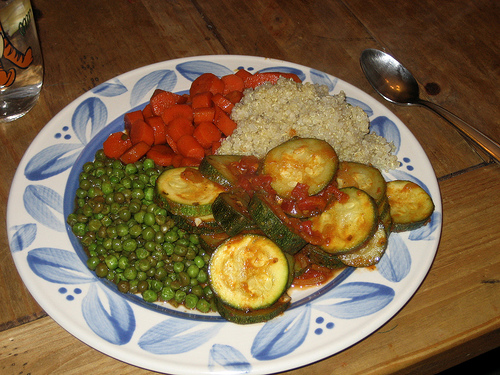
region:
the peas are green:
[107, 213, 219, 337]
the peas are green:
[79, 182, 171, 287]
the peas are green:
[65, 154, 202, 314]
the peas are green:
[125, 279, 214, 369]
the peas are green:
[99, 187, 276, 347]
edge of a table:
[436, 322, 468, 348]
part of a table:
[445, 251, 471, 296]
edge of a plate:
[358, 270, 405, 325]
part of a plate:
[151, 330, 175, 350]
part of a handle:
[466, 120, 489, 158]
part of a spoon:
[418, 93, 452, 120]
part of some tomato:
[283, 183, 315, 215]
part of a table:
[438, 268, 471, 308]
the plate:
[179, 310, 259, 373]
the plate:
[197, 296, 259, 316]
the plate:
[204, 290, 255, 338]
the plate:
[185, 285, 265, 356]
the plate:
[179, 301, 242, 341]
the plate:
[214, 287, 271, 373]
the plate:
[177, 247, 254, 307]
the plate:
[146, 257, 273, 356]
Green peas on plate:
[87, 165, 169, 285]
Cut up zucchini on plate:
[208, 232, 302, 304]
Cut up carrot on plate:
[108, 93, 208, 155]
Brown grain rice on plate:
[241, 82, 396, 162]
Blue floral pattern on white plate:
[24, 75, 391, 315]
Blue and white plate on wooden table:
[6, 52, 461, 373]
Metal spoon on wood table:
[373, 58, 496, 112]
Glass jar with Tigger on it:
[3, 0, 45, 116]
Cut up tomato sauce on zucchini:
[274, 182, 363, 224]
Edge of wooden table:
[420, 323, 497, 360]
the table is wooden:
[408, 311, 425, 327]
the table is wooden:
[402, 337, 412, 354]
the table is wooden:
[402, 330, 409, 339]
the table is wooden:
[402, 334, 421, 360]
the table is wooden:
[404, 332, 416, 354]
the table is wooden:
[410, 333, 433, 358]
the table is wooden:
[414, 338, 427, 358]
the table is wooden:
[413, 330, 425, 343]